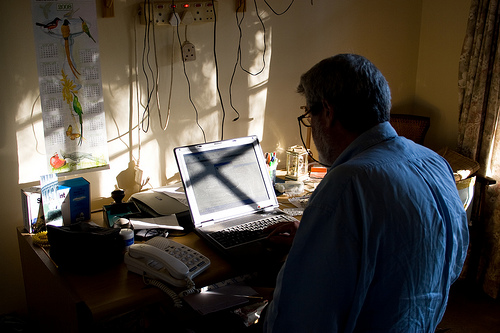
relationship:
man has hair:
[265, 52, 468, 332] [311, 30, 404, 135]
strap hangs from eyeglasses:
[295, 122, 327, 159] [298, 109, 312, 127]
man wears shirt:
[265, 52, 468, 332] [266, 135, 466, 330]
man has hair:
[265, 52, 468, 332] [301, 54, 397, 118]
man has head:
[265, 52, 468, 332] [295, 52, 395, 132]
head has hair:
[295, 52, 395, 132] [301, 54, 397, 118]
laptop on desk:
[170, 132, 301, 277] [11, 168, 497, 323]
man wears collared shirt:
[244, 30, 487, 332] [256, 132, 486, 318]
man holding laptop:
[265, 52, 468, 332] [173, 135, 301, 261]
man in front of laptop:
[265, 52, 468, 332] [173, 135, 301, 261]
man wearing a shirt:
[265, 52, 468, 332] [266, 135, 466, 330]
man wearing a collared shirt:
[265, 52, 468, 332] [265, 121, 470, 333]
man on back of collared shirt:
[265, 52, 468, 332] [265, 121, 470, 333]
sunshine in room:
[18, 10, 328, 232] [0, 2, 498, 332]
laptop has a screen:
[173, 135, 301, 261] [182, 143, 271, 216]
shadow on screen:
[182, 137, 268, 213] [182, 143, 271, 216]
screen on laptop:
[182, 143, 271, 216] [173, 135, 301, 261]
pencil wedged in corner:
[28, 244, 65, 302] [20, 228, 90, 315]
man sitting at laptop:
[265, 52, 468, 332] [176, 122, 327, 258]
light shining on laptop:
[173, 133, 293, 230] [171, 133, 303, 258]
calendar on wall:
[32, 1, 110, 174] [2, 3, 475, 322]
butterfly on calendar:
[58, 109, 90, 141] [32, 3, 112, 176]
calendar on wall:
[32, 3, 112, 176] [18, 13, 477, 243]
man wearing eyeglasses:
[265, 52, 468, 332] [271, 100, 331, 145]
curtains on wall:
[452, 0, 498, 157] [413, 0, 463, 117]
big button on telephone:
[168, 245, 207, 270] [125, 232, 210, 297]